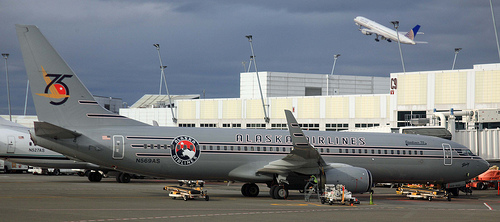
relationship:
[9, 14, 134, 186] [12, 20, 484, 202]
tail of plane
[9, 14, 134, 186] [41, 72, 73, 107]
tail says 75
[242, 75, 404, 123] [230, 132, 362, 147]
building has letters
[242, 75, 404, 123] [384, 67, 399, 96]
building has numbers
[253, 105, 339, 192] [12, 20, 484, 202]
wing of plane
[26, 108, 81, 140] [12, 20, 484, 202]
wing of plane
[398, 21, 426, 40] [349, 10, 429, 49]
wing of plane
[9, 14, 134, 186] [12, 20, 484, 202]
tail on plane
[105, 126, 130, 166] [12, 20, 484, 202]
door on plane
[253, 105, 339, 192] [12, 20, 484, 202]
wing on plane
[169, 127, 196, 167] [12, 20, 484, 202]
symbol on plane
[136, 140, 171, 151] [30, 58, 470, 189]
windows on gray plane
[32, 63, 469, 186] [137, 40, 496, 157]
airplane in airport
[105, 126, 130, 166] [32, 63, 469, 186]
door on airplane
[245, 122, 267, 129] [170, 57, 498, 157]
window on building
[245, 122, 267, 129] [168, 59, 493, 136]
window on building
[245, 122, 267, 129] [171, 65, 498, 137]
window on building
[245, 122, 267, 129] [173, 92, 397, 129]
window on building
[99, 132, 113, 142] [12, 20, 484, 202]
flag on plane